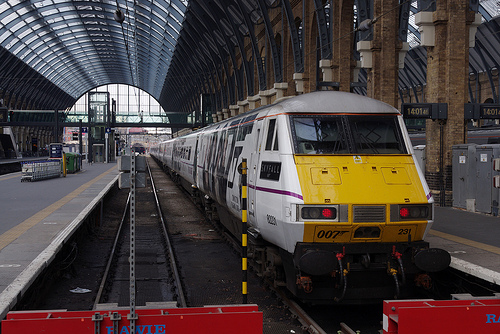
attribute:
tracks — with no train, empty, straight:
[90, 156, 189, 311]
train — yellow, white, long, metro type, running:
[148, 91, 452, 305]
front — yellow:
[282, 89, 436, 254]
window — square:
[289, 114, 353, 158]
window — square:
[347, 113, 409, 157]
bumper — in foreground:
[2, 302, 265, 333]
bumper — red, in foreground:
[383, 292, 499, 333]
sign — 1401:
[402, 105, 432, 118]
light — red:
[302, 207, 336, 219]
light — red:
[399, 206, 430, 221]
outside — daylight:
[62, 84, 172, 157]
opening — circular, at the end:
[63, 85, 173, 155]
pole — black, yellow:
[241, 160, 249, 303]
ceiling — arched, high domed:
[1, 0, 424, 122]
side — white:
[147, 107, 306, 256]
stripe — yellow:
[1, 163, 118, 249]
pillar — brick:
[426, 0, 470, 207]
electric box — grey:
[451, 143, 473, 212]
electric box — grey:
[476, 145, 499, 214]